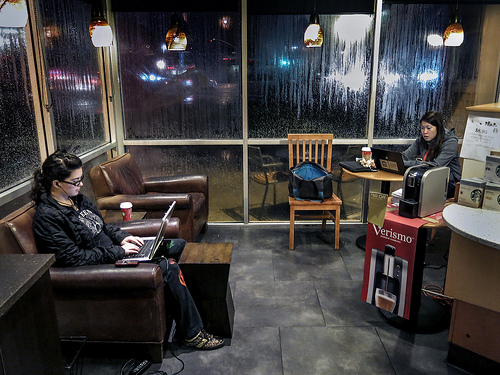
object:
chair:
[0, 199, 184, 362]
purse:
[288, 159, 333, 201]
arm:
[39, 224, 123, 268]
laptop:
[111, 199, 178, 262]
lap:
[161, 257, 179, 273]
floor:
[155, 223, 467, 374]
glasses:
[59, 178, 85, 186]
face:
[60, 167, 85, 197]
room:
[0, 0, 499, 374]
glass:
[372, 4, 480, 138]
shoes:
[180, 331, 225, 349]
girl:
[31, 149, 232, 350]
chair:
[90, 151, 209, 242]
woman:
[29, 149, 228, 349]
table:
[340, 167, 405, 251]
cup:
[118, 200, 135, 221]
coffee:
[375, 287, 398, 314]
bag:
[288, 160, 334, 202]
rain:
[0, 0, 477, 192]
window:
[118, 0, 244, 143]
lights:
[89, 22, 114, 49]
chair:
[287, 133, 342, 251]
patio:
[209, 147, 365, 224]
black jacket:
[32, 192, 132, 269]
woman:
[399, 111, 462, 189]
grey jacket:
[397, 129, 465, 184]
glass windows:
[247, 1, 369, 137]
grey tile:
[232, 280, 327, 328]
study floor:
[65, 227, 497, 373]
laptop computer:
[367, 147, 413, 176]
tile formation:
[279, 326, 395, 375]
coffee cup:
[360, 146, 373, 162]